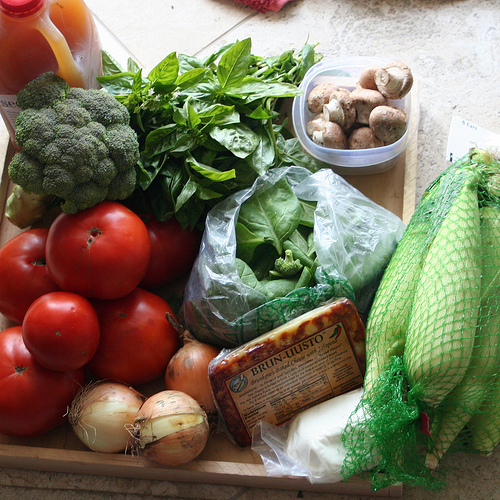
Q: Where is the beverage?
A: Behind the broccoli.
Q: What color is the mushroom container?
A: Clear.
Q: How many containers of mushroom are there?
A: 1.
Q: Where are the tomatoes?
A: In front of the broccoli.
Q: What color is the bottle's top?
A: Red.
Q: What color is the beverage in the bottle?
A: Brown.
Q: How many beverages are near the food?
A: 1.